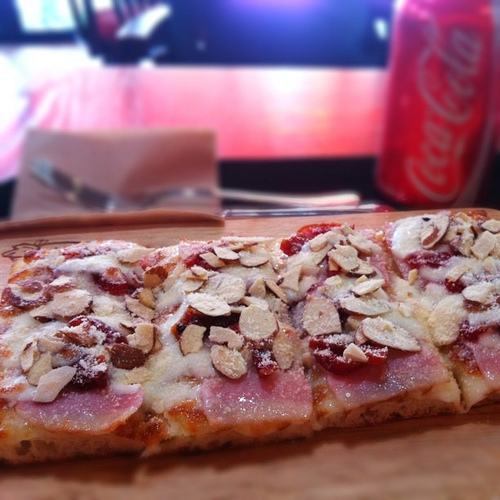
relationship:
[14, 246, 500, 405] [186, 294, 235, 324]
pizza with nuts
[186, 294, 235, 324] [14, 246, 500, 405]
nuts on pizza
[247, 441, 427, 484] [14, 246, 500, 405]
tray holding pizza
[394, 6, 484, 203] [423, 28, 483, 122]
coke has letters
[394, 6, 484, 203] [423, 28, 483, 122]
coke have letters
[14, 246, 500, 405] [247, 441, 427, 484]
pizza on tray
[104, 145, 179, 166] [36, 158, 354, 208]
napkin above fork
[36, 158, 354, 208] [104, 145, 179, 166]
fork sits on napkin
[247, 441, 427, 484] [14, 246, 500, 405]
tray with pizza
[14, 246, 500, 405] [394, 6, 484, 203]
pizza next to coke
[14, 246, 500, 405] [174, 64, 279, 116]
pizza near table